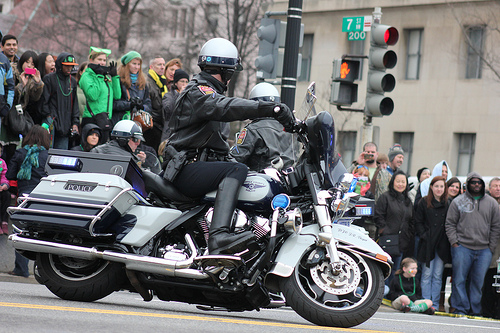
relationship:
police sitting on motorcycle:
[164, 38, 291, 259] [8, 37, 388, 327]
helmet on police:
[195, 39, 239, 70] [164, 38, 291, 259]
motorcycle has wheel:
[8, 37, 388, 327] [280, 234, 394, 321]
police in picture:
[164, 38, 291, 259] [8, 37, 388, 327]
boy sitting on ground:
[381, 250, 438, 320] [366, 299, 499, 329]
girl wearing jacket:
[77, 50, 109, 116] [80, 72, 123, 121]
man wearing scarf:
[140, 52, 173, 136] [144, 68, 169, 95]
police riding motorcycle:
[164, 38, 291, 259] [8, 37, 388, 327]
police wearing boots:
[164, 38, 291, 259] [214, 176, 256, 253]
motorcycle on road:
[8, 37, 388, 327] [4, 278, 495, 332]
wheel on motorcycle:
[280, 234, 394, 321] [8, 37, 388, 327]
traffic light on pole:
[370, 20, 392, 129] [355, 124, 375, 188]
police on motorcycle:
[164, 38, 291, 259] [8, 37, 388, 327]